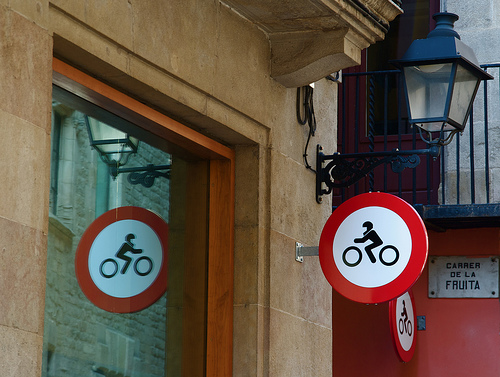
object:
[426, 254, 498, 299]
placard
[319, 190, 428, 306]
sign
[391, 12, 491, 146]
light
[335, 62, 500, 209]
railing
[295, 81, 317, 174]
wire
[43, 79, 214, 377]
window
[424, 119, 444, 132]
bulb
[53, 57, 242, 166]
trim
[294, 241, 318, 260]
bracket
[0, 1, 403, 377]
building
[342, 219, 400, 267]
biker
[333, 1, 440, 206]
door